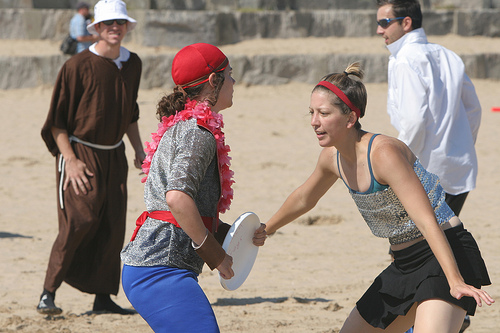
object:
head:
[307, 60, 368, 148]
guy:
[33, 0, 148, 315]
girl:
[257, 61, 497, 333]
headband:
[317, 80, 361, 119]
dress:
[38, 45, 144, 293]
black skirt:
[355, 222, 492, 329]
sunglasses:
[377, 17, 405, 28]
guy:
[376, 0, 481, 219]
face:
[374, 5, 403, 45]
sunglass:
[85, 12, 147, 32]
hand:
[450, 282, 496, 307]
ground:
[1, 98, 499, 332]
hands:
[252, 223, 268, 247]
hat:
[85, 0, 138, 35]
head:
[94, 17, 130, 45]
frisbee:
[217, 211, 265, 291]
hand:
[215, 253, 235, 280]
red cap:
[170, 42, 228, 87]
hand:
[62, 158, 94, 195]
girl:
[120, 42, 237, 333]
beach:
[4, 108, 497, 328]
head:
[170, 41, 240, 110]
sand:
[272, 259, 335, 321]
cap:
[171, 42, 229, 88]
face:
[308, 93, 348, 148]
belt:
[130, 210, 218, 241]